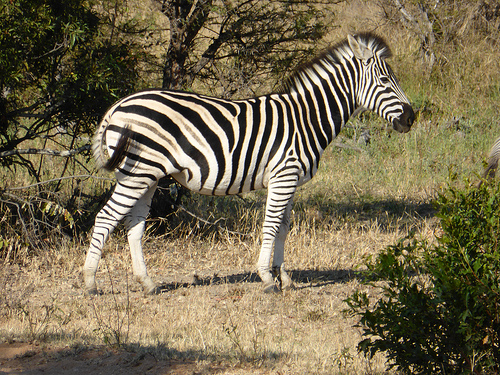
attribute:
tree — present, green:
[0, 1, 140, 235]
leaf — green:
[109, 91, 122, 101]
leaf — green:
[70, 33, 78, 51]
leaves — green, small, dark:
[1, 1, 136, 101]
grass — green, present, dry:
[317, 88, 499, 199]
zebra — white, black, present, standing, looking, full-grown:
[82, 30, 416, 298]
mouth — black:
[394, 101, 416, 134]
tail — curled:
[92, 107, 133, 171]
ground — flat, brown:
[4, 189, 443, 373]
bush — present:
[347, 183, 498, 374]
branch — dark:
[189, 0, 318, 92]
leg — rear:
[77, 172, 140, 297]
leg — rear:
[127, 189, 162, 296]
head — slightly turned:
[357, 30, 415, 135]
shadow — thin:
[156, 266, 427, 292]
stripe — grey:
[117, 116, 178, 150]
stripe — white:
[118, 106, 189, 149]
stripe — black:
[109, 119, 178, 150]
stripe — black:
[120, 105, 184, 143]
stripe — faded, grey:
[172, 112, 208, 148]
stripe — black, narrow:
[270, 197, 291, 204]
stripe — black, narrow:
[271, 179, 298, 185]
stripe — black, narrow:
[264, 217, 282, 226]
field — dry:
[2, 1, 498, 374]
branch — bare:
[1, 142, 91, 164]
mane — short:
[277, 32, 393, 91]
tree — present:
[141, 4, 327, 241]